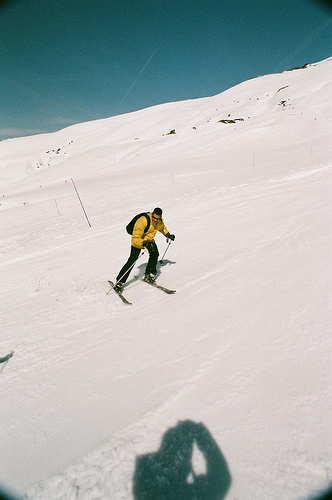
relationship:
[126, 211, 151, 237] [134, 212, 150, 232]
backpack worn on back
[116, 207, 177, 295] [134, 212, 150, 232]
skier has back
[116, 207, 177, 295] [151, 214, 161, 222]
skier wearing sunglasses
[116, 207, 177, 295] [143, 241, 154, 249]
skier wearing right glove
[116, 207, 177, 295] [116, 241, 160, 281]
skier wearing pants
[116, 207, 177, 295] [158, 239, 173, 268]
skier holding ski pole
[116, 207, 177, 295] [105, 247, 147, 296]
skier holding ski pole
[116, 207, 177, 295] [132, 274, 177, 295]
skier standing on left ski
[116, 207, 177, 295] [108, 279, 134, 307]
skier standing on right ski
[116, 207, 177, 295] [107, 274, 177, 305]
skier on top of skis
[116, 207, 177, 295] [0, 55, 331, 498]
skier looking down slope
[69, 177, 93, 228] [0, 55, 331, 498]
pole marking slope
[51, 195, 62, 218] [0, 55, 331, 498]
pole marking slope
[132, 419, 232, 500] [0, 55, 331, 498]
shadow on top of slope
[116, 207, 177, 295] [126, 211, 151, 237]
skier has backpack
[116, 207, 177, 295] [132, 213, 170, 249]
skier wearing ski jacket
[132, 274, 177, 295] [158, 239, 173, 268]
left ski next to ski pole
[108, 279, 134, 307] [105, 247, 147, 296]
right ski next to ski pole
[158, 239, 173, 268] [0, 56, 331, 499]
ski pole located in snow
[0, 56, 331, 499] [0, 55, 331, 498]
snow covering slope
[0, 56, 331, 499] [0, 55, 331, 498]
snow on top of slope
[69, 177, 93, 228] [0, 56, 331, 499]
pole standing in snow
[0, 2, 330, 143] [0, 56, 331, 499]
sky against snow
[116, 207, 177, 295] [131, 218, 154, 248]
skier has arm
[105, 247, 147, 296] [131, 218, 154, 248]
ski pole in arm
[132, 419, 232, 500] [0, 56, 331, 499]
shadow on top of snow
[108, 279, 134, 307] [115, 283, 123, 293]
right ski worn on foot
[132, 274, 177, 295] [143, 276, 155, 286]
left ski worn on foot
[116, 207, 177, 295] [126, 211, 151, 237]
skier wearing backpack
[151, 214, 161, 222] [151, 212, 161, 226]
sunglasses on front of face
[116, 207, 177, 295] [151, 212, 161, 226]
skier has face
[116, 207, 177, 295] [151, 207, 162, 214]
skier has hair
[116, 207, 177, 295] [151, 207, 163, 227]
skier has head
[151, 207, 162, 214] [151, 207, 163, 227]
hair on top of head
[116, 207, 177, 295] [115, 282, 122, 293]
skier wearing boot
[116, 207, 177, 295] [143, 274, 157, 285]
skier wearing boot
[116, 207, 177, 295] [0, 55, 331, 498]
skier skiing down slope